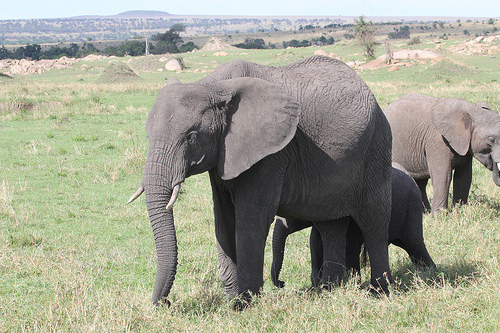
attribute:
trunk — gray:
[142, 145, 178, 308]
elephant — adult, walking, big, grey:
[122, 53, 392, 313]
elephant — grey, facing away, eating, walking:
[381, 90, 500, 219]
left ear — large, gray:
[215, 74, 305, 182]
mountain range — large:
[2, 7, 485, 39]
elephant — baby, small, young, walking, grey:
[269, 159, 443, 291]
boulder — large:
[165, 56, 184, 73]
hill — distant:
[68, 7, 180, 18]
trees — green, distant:
[0, 38, 202, 61]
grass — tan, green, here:
[0, 72, 500, 331]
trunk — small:
[270, 217, 286, 289]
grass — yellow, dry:
[3, 78, 163, 121]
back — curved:
[223, 53, 374, 131]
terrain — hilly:
[0, 20, 500, 88]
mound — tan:
[196, 35, 234, 57]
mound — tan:
[372, 47, 439, 68]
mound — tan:
[457, 32, 499, 52]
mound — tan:
[1, 58, 39, 75]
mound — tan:
[50, 53, 75, 72]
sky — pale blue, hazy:
[0, 0, 496, 19]